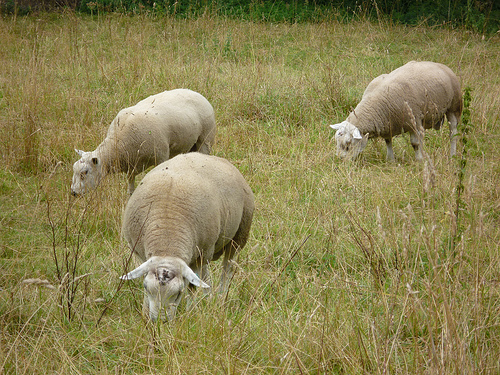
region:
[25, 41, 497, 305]
three very big sheeps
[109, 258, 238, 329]
a sheep white head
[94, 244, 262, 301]
pointy white sheep ears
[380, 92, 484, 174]
a sheep short legs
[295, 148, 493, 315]
green grass that the sheep eats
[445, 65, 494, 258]
a tall green weed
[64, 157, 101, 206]
a sheep black eye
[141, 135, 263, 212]
the white back of a sheep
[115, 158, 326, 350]
a sheep grazing in a field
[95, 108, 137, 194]
a sheep white neck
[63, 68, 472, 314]
three sheep standing in a field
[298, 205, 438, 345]
long green grass of the field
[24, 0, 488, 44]
several green trees growing in the background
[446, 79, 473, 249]
single green plant shoot in the field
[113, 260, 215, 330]
white head of a sheep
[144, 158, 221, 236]
beige fleece of a sheep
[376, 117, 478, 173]
white legs of the sheep on the right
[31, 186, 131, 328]
a dead brown plant sticking out of the ground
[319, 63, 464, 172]
a sheep with its head to the ground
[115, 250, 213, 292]
white angled ears of the sheep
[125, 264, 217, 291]
The ears of the sheep in the front.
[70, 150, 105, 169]
The ears of the sheep on the left.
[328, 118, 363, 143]
The ears of the sheep on the right.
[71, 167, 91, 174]
The eye of the sheep on the left.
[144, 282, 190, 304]
The eyes of the sheep in the front.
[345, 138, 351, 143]
The eye of the sheep on the right.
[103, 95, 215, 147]
The body of the sheep on the left.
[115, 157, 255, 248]
The body of the sheep in the front.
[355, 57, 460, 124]
The body of the sheep on the right.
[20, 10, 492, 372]
The grassy pasture the sheep are standing in.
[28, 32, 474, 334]
three sheep eating grass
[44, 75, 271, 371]
two sheep eating grass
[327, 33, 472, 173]
a sheep eating grass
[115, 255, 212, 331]
the head of a sheep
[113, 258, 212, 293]
the ears of a sheep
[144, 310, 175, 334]
the nose of a sheep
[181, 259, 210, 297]
the ear of a sheep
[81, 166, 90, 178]
the eye of a sheep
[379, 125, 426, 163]
the front legs of a sheep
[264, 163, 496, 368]
a tall stand of grass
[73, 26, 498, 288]
three sheep in the grass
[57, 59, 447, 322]
the sheep are eating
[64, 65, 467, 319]
the sheep are grazing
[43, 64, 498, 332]
these sheeps are white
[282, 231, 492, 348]
the grass is green and brown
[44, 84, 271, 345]
these sheep have been sheared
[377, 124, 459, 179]
the sheep has white legs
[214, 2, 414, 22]
green grass in the picture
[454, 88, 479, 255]
a weed growing in the grass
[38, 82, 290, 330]
sheep eat grass as a food source